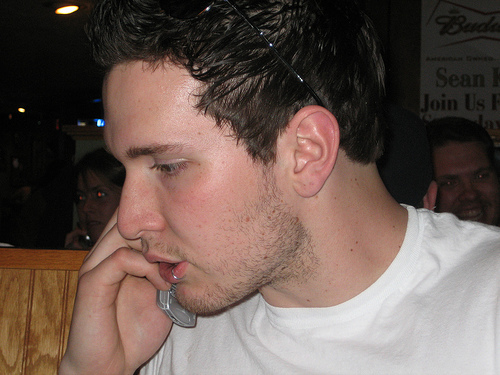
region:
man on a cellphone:
[106, 174, 218, 340]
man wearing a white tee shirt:
[298, 279, 462, 368]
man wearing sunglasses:
[157, 8, 293, 71]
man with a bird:
[218, 153, 320, 276]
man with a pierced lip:
[165, 261, 184, 286]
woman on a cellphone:
[60, 168, 129, 243]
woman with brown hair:
[64, 150, 140, 207]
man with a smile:
[455, 188, 498, 235]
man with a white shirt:
[281, 274, 434, 366]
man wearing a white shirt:
[317, 248, 439, 353]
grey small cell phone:
[157, 280, 197, 327]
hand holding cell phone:
[66, 220, 193, 373]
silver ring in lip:
[170, 268, 182, 283]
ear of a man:
[295, 105, 338, 197]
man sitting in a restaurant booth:
[77, 23, 494, 374]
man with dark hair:
[64, 19, 494, 373]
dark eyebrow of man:
[120, 143, 183, 153]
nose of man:
[115, 169, 157, 239]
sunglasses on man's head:
[190, 6, 332, 110]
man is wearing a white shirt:
[84, 26, 497, 366]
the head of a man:
[99, 1, 402, 317]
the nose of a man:
[112, 183, 168, 240]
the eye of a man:
[148, 153, 199, 177]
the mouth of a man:
[142, 244, 187, 284]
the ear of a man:
[287, 101, 340, 202]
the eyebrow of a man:
[124, 139, 186, 157]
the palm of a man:
[106, 282, 157, 348]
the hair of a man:
[91, 1, 385, 166]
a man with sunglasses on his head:
[16, 4, 408, 304]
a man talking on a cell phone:
[91, 85, 251, 351]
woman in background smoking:
[64, 165, 120, 239]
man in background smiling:
[428, 115, 497, 225]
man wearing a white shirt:
[72, 6, 487, 359]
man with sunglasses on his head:
[78, 5, 418, 205]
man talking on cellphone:
[55, 10, 453, 350]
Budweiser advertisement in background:
[413, 6, 495, 133]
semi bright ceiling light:
[53, 1, 90, 28]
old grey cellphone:
[152, 271, 209, 332]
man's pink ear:
[273, 97, 360, 202]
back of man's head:
[393, 112, 455, 212]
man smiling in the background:
[427, 110, 498, 227]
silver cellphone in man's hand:
[155, 278, 202, 328]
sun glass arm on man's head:
[205, 3, 327, 110]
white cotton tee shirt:
[142, 205, 493, 374]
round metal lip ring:
[165, 261, 188, 283]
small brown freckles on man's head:
[97, 83, 399, 305]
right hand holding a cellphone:
[67, 191, 177, 373]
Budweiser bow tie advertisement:
[420, 0, 498, 52]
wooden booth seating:
[1, 248, 83, 374]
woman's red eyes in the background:
[73, 184, 112, 207]